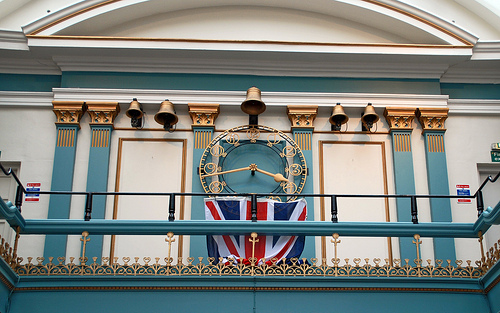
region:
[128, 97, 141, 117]
the brass large bell on the wall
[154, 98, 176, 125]
the brass large bell on the wall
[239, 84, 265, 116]
the brass large bell on the wall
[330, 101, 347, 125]
the brass large bell on the wall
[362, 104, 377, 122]
the brass large bell on the wall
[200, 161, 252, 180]
the large gold hand on the clock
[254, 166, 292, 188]
the large gold hand on the clock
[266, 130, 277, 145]
the gold 1 on the clock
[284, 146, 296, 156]
the gold 2 on the clock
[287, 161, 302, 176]
the gold 3 on the clock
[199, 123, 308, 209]
metal clock face reading about a quarter to four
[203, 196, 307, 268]
flag of the United Kingdom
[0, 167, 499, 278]
black, blue, and gold railing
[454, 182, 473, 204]
red, white, and blue sign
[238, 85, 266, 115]
gold colored metal bell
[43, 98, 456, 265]
blue and gold decorative pillars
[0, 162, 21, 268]
white doorway behind railing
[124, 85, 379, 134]
five gold colored bells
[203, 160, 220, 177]
the number nine in gold colored metal work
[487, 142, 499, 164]
green sign with white lettering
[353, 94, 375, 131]
light on the building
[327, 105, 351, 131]
light on the building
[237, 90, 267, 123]
light on the building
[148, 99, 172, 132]
light on the building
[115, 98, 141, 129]
light on the building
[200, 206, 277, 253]
flag on the building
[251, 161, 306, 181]
hand of the clock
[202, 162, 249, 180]
hand of the clock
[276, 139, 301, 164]
time on the clock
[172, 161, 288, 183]
time on the clock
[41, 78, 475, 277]
balcony overlooking an area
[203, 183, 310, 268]
flag hanging from a balcony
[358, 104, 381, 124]
bell on the wall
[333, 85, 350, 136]
bell on the wall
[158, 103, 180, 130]
bell on the wall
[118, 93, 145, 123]
bell on the wall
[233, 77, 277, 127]
bell on the wall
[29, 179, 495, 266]
railing on the balcony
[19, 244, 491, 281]
decorative pattern underneath railing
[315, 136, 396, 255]
rectangle outlined in brass color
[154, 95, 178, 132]
copper bell attached to the wall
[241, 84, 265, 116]
copper bell attached to the wall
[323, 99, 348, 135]
copper bell attached to the wall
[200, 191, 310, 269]
blue white and red flag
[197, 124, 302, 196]
large gold clock on the wall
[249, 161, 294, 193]
gold hour hand of clock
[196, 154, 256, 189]
gold minute hand of clock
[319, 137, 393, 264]
gold rectangle decal on wall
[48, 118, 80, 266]
baby blue pillar on wall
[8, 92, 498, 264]
blue and white wall